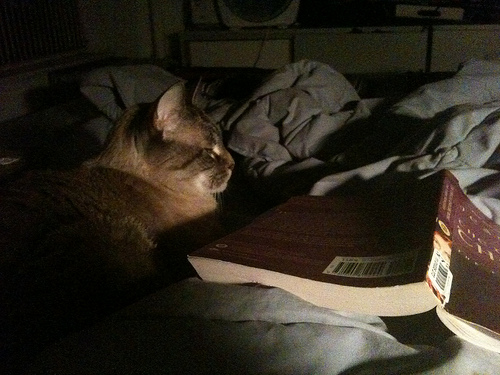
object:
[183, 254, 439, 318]
paper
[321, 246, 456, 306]
barcode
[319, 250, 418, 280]
upc code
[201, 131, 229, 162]
eye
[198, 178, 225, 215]
whiskers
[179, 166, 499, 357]
book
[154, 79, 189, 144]
ear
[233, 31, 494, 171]
blanket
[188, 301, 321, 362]
cover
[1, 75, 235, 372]
cat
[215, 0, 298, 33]
fan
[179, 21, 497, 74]
shelf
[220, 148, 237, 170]
nose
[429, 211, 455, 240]
sticker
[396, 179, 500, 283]
lettering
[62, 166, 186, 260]
stripes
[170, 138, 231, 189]
stripe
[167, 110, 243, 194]
face